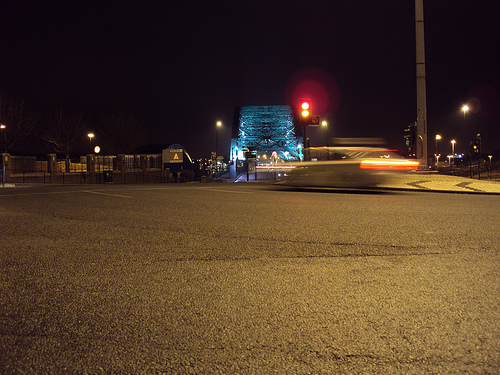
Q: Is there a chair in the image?
A: No, there are no chairs.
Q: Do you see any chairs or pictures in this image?
A: No, there are no chairs or pictures.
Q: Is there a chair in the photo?
A: No, there are no chairs.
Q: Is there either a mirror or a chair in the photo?
A: No, there are no chairs or mirrors.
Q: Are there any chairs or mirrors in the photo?
A: No, there are no chairs or mirrors.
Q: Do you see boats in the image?
A: No, there are no boats.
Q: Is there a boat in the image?
A: No, there are no boats.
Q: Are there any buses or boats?
A: No, there are no boats or buses.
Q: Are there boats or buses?
A: No, there are no boats or buses.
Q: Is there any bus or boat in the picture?
A: No, there are no boats or buses.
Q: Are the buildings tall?
A: Yes, the buildings are tall.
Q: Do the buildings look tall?
A: Yes, the buildings are tall.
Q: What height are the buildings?
A: The buildings are tall.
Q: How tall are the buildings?
A: The buildings are tall.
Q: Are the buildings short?
A: No, the buildings are tall.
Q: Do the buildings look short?
A: No, the buildings are tall.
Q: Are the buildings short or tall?
A: The buildings are tall.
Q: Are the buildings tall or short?
A: The buildings are tall.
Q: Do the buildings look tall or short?
A: The buildings are tall.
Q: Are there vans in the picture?
A: No, there are no vans.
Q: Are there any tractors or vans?
A: No, there are no vans or tractors.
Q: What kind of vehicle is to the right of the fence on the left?
A: The vehicle is a car.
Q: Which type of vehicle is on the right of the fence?
A: The vehicle is a car.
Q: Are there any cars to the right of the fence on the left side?
A: Yes, there is a car to the right of the fence.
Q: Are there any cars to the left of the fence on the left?
A: No, the car is to the right of the fence.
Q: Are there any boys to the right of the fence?
A: No, there is a car to the right of the fence.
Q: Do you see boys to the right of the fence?
A: No, there is a car to the right of the fence.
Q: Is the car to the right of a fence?
A: Yes, the car is to the right of a fence.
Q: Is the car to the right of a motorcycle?
A: No, the car is to the right of a fence.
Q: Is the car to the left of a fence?
A: No, the car is to the right of a fence.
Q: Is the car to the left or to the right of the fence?
A: The car is to the right of the fence.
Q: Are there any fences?
A: Yes, there is a fence.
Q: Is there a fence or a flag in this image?
A: Yes, there is a fence.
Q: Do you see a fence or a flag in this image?
A: Yes, there is a fence.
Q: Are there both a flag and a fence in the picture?
A: No, there is a fence but no flags.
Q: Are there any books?
A: No, there are no books.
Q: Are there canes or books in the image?
A: No, there are no books or canes.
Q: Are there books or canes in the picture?
A: No, there are no books or canes.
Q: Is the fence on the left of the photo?
A: Yes, the fence is on the left of the image.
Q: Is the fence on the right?
A: No, the fence is on the left of the image.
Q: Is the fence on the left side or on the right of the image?
A: The fence is on the left of the image.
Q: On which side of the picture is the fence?
A: The fence is on the left of the image.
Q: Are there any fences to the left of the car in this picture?
A: Yes, there is a fence to the left of the car.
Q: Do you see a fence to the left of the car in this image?
A: Yes, there is a fence to the left of the car.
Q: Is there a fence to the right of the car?
A: No, the fence is to the left of the car.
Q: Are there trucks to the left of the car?
A: No, there is a fence to the left of the car.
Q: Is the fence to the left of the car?
A: Yes, the fence is to the left of the car.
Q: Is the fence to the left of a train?
A: No, the fence is to the left of the car.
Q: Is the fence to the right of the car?
A: No, the fence is to the left of the car.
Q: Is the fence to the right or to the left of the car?
A: The fence is to the left of the car.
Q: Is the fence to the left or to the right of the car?
A: The fence is to the left of the car.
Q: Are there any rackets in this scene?
A: No, there are no rackets.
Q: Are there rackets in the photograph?
A: No, there are no rackets.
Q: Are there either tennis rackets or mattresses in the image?
A: No, there are no tennis rackets or mattresses.